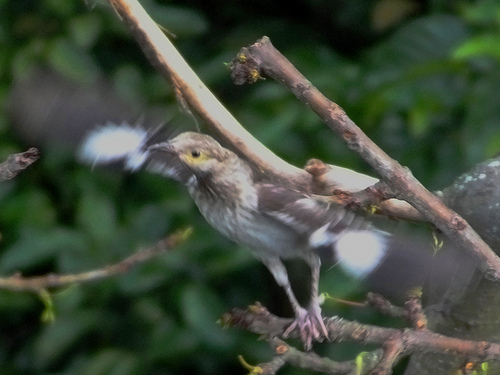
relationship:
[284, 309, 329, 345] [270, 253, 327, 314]
feet on legs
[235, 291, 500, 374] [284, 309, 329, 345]
branch under feet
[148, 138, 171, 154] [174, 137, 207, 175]
beak on face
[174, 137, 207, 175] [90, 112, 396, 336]
face of bird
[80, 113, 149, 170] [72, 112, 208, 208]
spot on wing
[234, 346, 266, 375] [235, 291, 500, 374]
blossom on branch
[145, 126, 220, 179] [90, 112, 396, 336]
head of bird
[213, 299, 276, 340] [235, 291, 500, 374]
tip of th branch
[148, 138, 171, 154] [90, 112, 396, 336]
beak of bird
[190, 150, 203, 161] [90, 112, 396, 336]
eye of bird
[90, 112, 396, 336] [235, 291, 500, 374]
bird perched on branch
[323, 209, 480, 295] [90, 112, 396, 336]
tail of bird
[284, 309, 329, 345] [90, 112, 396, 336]
feet of bird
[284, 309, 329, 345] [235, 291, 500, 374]
feet are releasing branch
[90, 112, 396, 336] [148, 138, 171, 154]
bird has a beak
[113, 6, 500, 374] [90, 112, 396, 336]
branches beside bird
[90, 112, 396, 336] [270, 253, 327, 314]
bird has legs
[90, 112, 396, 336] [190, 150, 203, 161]
bird has an eye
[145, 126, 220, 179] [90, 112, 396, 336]
head of a bird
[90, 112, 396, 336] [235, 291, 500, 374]
bird on a branch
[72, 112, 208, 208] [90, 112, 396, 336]
wing of a bird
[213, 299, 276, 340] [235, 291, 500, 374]
tip of branch